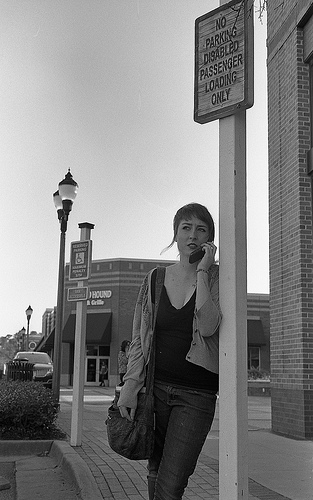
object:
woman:
[102, 194, 237, 499]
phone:
[184, 233, 221, 273]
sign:
[183, 0, 262, 125]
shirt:
[144, 261, 222, 396]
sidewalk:
[55, 392, 259, 498]